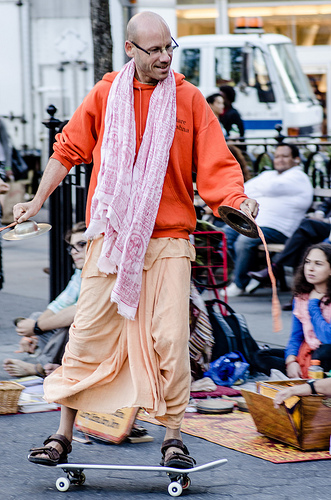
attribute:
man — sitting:
[215, 142, 314, 300]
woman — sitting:
[253, 239, 330, 379]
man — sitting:
[6, 219, 93, 381]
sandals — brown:
[26, 432, 194, 470]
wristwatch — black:
[305, 377, 317, 397]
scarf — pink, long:
[82, 56, 177, 318]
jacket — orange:
[48, 67, 248, 241]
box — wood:
[241, 377, 329, 452]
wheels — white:
[56, 476, 182, 497]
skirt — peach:
[40, 231, 199, 432]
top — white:
[236, 164, 315, 238]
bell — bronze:
[2, 219, 52, 242]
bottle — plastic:
[306, 358, 326, 382]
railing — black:
[39, 103, 94, 306]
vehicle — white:
[167, 30, 323, 158]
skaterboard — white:
[28, 457, 227, 495]